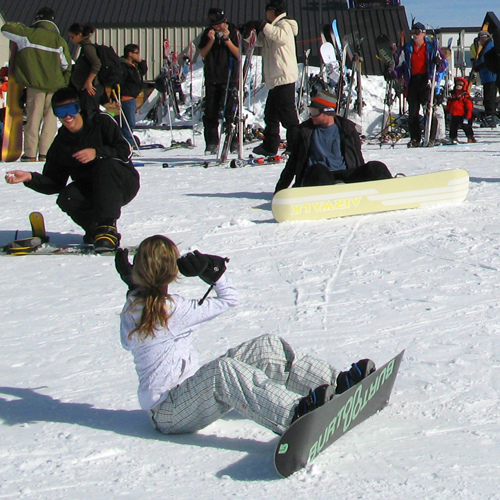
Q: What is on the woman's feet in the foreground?
A: Snowboard.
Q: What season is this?
A: Winter.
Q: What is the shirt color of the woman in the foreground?
A: White.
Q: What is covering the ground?
A: Snow.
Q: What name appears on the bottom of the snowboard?
A: Burton.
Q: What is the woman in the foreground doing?
A: Sitting down.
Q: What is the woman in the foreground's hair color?
A: Blonde.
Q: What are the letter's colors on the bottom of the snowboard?
A: Green.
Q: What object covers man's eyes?
A: Blue ski goggles.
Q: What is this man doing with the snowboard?
A: Taking break.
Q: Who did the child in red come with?
A: Parent red.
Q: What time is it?
A: Afternoon.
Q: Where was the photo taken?
A: Outside somewhere.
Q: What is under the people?
A: Snow.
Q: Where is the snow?
A: On the ground.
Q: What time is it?
A: Afternoon.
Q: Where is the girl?
A: On the ground.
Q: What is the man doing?
A: Giggling.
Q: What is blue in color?
A: The sky.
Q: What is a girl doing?
A: Snowboarding.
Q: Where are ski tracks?
A: On the snow.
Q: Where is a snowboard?
A: Under woman's feet.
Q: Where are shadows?
A: On the snow.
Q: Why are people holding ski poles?
A: To ski.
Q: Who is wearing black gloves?
A: Woman in white shirt.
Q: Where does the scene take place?
A: At a ski slope.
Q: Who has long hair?
A: Woman on the ground.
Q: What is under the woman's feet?
A: A snowboard.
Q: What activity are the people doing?
A: Snowboarding.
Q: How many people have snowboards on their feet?
A: 2.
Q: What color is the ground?
A: White.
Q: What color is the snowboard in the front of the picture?
A: Black.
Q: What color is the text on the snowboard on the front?
A: Green.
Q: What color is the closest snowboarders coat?
A: White.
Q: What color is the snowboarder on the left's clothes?
A: Black.